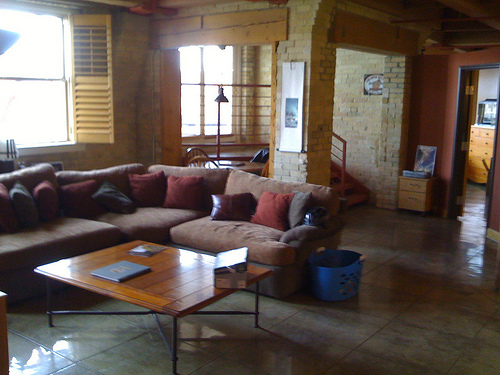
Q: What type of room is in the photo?
A: Living room.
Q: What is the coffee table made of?
A: Wood.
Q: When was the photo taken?
A: During daylight hours.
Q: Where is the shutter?
A: Near the window.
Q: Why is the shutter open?
A: To let light into the room.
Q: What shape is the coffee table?
A: Square.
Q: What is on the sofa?
A: Pillows.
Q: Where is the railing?
A: By the steps.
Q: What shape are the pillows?
A: Square.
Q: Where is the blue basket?
A: Next to the sectional sofa.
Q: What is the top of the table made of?
A: Wood.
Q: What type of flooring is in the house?
A: Tile.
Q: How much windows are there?
A: Two.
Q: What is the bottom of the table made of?
A: Metal.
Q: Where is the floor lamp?
A: Behind the sofa.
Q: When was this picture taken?
A: Daytime.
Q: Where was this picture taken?
A: A house.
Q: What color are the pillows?
A: Red and green.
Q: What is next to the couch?
A: Laundry hamper.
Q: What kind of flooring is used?
A: Tile.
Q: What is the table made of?
A: Wood.